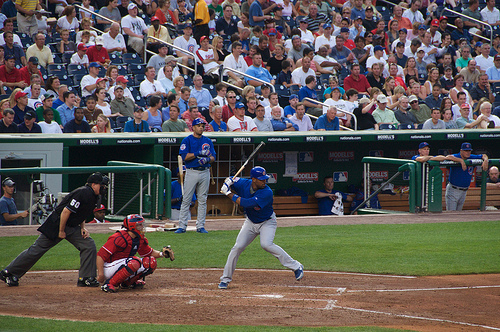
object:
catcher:
[93, 210, 176, 293]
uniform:
[96, 228, 159, 288]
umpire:
[2, 170, 113, 290]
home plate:
[249, 291, 285, 302]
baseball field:
[1, 207, 499, 331]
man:
[444, 141, 490, 213]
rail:
[425, 158, 499, 169]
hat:
[459, 139, 475, 155]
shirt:
[448, 152, 486, 191]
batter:
[218, 163, 307, 289]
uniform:
[218, 175, 304, 281]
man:
[171, 116, 221, 235]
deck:
[0, 210, 499, 242]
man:
[267, 105, 300, 134]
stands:
[0, 2, 498, 133]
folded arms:
[272, 122, 301, 133]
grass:
[2, 220, 499, 277]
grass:
[0, 315, 420, 331]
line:
[345, 278, 499, 299]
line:
[335, 303, 499, 330]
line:
[257, 282, 346, 293]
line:
[1, 308, 100, 324]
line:
[4, 263, 419, 281]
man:
[312, 175, 357, 216]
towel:
[331, 191, 347, 217]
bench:
[270, 184, 499, 222]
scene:
[2, 0, 499, 331]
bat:
[219, 139, 266, 197]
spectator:
[138, 62, 166, 98]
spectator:
[342, 63, 374, 93]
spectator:
[315, 105, 341, 131]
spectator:
[367, 60, 385, 93]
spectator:
[422, 107, 449, 131]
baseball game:
[0, 129, 500, 330]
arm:
[472, 152, 492, 174]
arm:
[445, 152, 469, 172]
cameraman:
[2, 178, 38, 226]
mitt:
[160, 244, 175, 264]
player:
[168, 168, 197, 221]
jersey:
[168, 176, 200, 209]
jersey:
[227, 175, 276, 224]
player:
[351, 178, 384, 215]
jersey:
[349, 187, 381, 215]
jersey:
[317, 187, 350, 217]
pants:
[219, 208, 257, 279]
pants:
[194, 169, 212, 228]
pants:
[445, 183, 457, 211]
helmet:
[249, 163, 270, 185]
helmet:
[191, 115, 208, 128]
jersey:
[97, 227, 155, 263]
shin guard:
[109, 259, 141, 288]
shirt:
[34, 185, 102, 243]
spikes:
[172, 227, 187, 235]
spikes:
[197, 226, 209, 237]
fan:
[122, 2, 148, 42]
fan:
[86, 36, 113, 65]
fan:
[386, 17, 400, 47]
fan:
[171, 22, 200, 61]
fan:
[146, 13, 173, 61]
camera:
[27, 176, 65, 226]